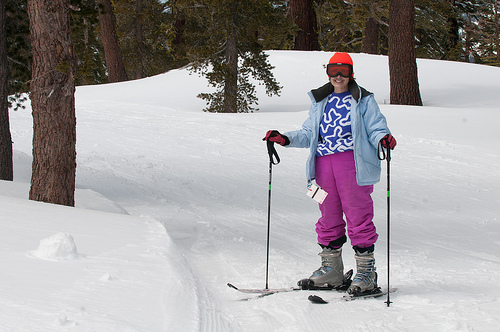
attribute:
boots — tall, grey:
[297, 242, 378, 293]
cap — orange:
[329, 46, 355, 70]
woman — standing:
[265, 62, 407, 297]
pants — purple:
[313, 148, 379, 249]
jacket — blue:
[278, 83, 391, 191]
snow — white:
[0, 43, 498, 327]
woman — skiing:
[244, 40, 426, 308]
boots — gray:
[295, 241, 382, 296]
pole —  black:
[380, 145, 395, 305]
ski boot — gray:
[296, 241, 345, 291]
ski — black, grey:
[307, 285, 398, 307]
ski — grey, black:
[225, 278, 361, 299]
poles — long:
[205, 111, 427, 313]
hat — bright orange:
[328, 50, 354, 66]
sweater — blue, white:
[292, 87, 372, 154]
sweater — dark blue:
[317, 89, 352, 156]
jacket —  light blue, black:
[271, 85, 398, 180]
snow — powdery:
[38, 201, 89, 273]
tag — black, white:
[303, 182, 327, 207]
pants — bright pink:
[309, 162, 376, 250]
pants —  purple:
[310, 150, 387, 252]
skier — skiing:
[295, 47, 393, 271]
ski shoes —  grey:
[299, 244, 381, 294]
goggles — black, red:
[303, 63, 363, 96]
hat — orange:
[327, 51, 354, 78]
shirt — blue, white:
[321, 96, 361, 158]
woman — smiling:
[263, 51, 394, 296]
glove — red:
[265, 128, 289, 145]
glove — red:
[378, 131, 395, 147]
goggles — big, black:
[327, 64, 351, 76]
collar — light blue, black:
[304, 81, 362, 101]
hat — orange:
[326, 50, 354, 82]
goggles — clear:
[323, 62, 357, 73]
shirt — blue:
[312, 88, 354, 153]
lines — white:
[319, 95, 344, 148]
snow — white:
[27, 225, 82, 262]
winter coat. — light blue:
[283, 81, 398, 184]